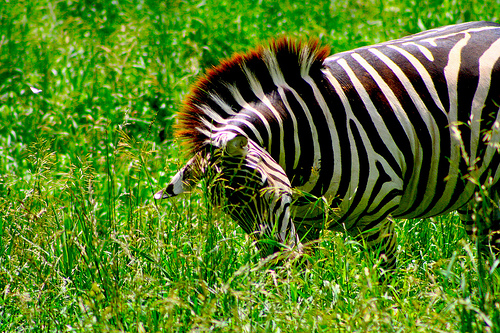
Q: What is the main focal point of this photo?
A: A black and white zebra.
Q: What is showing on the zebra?
A: The backbone of the zebra.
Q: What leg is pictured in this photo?
A: The zebras left front leg.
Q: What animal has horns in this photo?
A: The black and white zebra's head.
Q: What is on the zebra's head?
A: A black and white mane.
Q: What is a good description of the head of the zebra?
A: Black and white.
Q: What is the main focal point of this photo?
A: The black and white body of a zebra.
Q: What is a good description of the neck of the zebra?
A: Black and white.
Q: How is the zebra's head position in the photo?
A: Downward towards the grass.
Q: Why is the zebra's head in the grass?
A: To eat.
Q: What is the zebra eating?
A: Tall green grass.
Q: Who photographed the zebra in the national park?
A: A tourist.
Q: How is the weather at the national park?
A: Sunny and clear.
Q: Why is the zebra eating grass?
A: To satisfy the appetite.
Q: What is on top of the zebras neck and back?
A: Brown and white mane.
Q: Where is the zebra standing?
A: In a tall grassy field.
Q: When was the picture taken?
A: Daytime.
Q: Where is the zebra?
A: In the fields.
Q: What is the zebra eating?
A: Grass.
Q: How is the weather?
A: Sunny.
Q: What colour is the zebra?
A: Black and white.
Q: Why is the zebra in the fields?
A: It is feeding on the grass.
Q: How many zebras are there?
A: One.